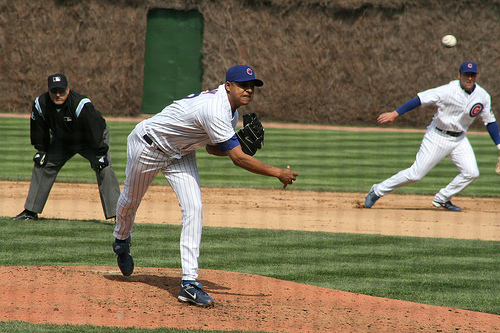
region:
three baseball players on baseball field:
[12, 61, 496, 306]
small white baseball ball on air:
[440, 29, 462, 53]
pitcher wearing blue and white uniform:
[107, 63, 292, 304]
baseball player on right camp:
[350, 56, 498, 214]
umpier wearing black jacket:
[11, 66, 125, 224]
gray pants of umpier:
[21, 142, 121, 222]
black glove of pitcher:
[240, 109, 270, 153]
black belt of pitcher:
[131, 128, 186, 165]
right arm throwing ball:
[212, 116, 293, 190]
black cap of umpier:
[44, 71, 68, 101]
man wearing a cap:
[350, 55, 488, 235]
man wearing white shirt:
[360, 55, 496, 205]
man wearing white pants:
[351, 60, 488, 215]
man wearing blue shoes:
[356, 58, 482, 224]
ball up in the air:
[426, 31, 461, 51]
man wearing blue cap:
[110, 50, 315, 310]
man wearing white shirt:
[110, 55, 306, 315]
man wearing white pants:
[115, 47, 296, 327]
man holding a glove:
[106, 57, 296, 330]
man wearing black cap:
[0, 66, 112, 213]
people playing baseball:
[3, 3, 498, 329]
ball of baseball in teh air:
[437, 28, 461, 53]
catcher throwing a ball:
[104, 13, 465, 310]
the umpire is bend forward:
[16, 66, 124, 233]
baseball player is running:
[359, 50, 499, 221]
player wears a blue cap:
[193, 54, 273, 157]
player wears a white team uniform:
[354, 46, 499, 211]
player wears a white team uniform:
[100, 48, 298, 313]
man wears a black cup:
[19, 68, 113, 163]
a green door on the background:
[130, 2, 210, 106]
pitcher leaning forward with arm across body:
[106, 58, 302, 303]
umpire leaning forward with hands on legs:
[15, 70, 120, 215]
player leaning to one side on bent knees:
[360, 55, 496, 211]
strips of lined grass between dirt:
[0, 110, 495, 330]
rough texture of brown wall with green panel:
[1, 5, 492, 122]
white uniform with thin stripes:
[110, 80, 235, 272]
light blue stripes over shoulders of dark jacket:
[26, 70, 106, 162]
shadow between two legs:
[100, 260, 262, 305]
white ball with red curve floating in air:
[437, 31, 454, 43]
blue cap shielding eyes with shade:
[225, 58, 263, 104]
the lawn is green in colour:
[295, 120, 372, 182]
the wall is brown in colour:
[278, 13, 370, 123]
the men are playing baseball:
[42, 28, 498, 332]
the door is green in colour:
[141, 5, 199, 90]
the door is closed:
[151, 7, 202, 89]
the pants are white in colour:
[121, 135, 211, 280]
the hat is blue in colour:
[214, 67, 267, 79]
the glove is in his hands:
[225, 115, 265, 145]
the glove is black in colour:
[213, 113, 279, 153]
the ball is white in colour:
[431, 29, 460, 47]